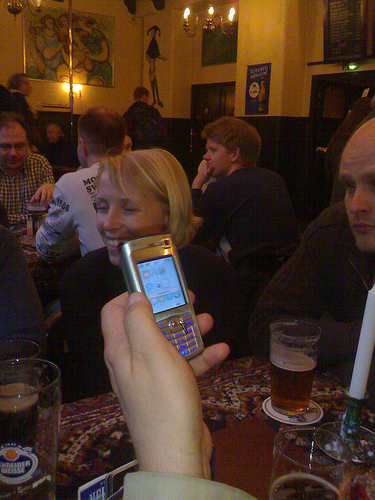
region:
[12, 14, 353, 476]
a group of people in restaurant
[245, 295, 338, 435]
a pint glass of beer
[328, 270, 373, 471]
a candle in holder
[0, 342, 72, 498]
an empty pint glass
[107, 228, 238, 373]
a small silver cell phone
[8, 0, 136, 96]
a large rectangular picture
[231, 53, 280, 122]
a beer advertisement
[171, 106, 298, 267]
a young blonde man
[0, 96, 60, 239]
a man wearing plaid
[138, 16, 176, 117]
an image of a jester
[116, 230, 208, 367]
Cell phone is lit up.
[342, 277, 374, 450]
White candle on table.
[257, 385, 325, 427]
Glass is sitting on coaster.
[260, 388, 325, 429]
Coaster is made from paper.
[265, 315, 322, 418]
Glass is half full.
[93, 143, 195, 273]
The woman is smiling.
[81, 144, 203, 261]
Woman has blonde hair.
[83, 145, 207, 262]
Woman's hair is short.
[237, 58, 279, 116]
There's a poster hanging on the wall.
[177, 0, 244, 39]
Hanging lights are turned on.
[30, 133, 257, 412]
Blonde woman smile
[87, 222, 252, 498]
Hand holding a cell phone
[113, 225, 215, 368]
Phone color is silver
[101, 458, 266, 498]
Sleeve color is tan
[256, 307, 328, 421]
Glass of beer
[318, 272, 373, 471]
candle in the candlestick is unlit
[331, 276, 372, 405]
Candle is long and white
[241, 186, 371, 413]
Man wears a brown jacket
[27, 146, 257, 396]
Woman is blonde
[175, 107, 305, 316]
Man has left hand on chin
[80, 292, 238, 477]
hand is holding cellphone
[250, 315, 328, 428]
beer glass is half full